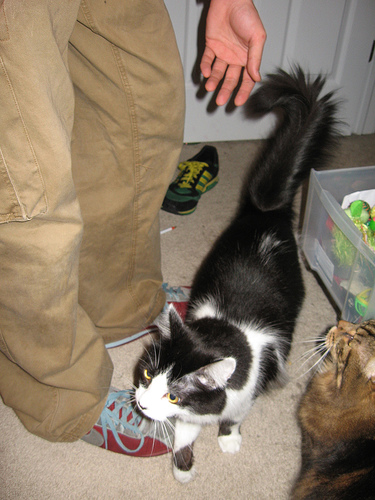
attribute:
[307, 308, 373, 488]
cat — brown, on right side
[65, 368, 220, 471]
shoes — gray, red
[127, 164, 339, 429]
cat — brown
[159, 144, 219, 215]
shoe — black, yellow, green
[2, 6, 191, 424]
pants — cargo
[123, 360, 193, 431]
markings — white